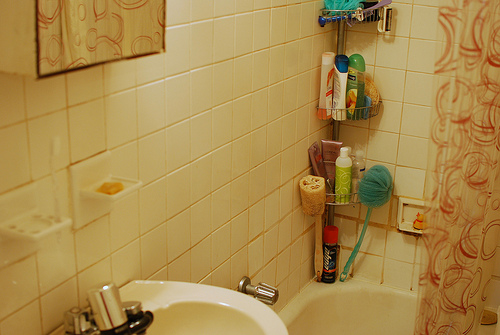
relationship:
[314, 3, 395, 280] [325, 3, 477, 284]
shower caddy against wall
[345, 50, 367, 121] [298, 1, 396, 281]
shower gel in container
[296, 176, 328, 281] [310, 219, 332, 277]
loofah on handle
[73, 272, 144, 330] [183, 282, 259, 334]
faucet on sink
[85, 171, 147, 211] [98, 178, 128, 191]
dish holding soap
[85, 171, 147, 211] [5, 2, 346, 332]
dish on wall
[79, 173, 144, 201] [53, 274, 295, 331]
dish for sink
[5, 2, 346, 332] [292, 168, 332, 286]
wall with loofah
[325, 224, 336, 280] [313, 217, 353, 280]
can of gel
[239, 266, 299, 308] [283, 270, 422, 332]
knob for tub